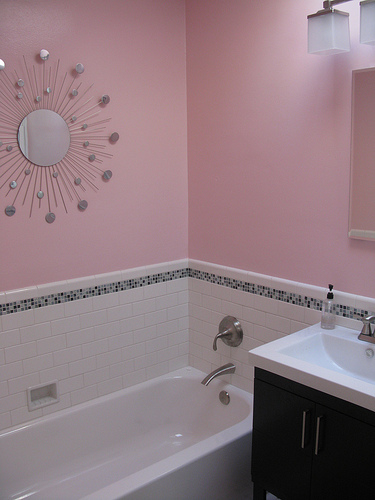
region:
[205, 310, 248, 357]
A bath tube water control lever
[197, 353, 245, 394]
A bathtub water faucet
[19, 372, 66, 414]
A bathtub soap dish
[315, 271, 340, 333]
A soap dispenser on a sink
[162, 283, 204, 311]
White tile on a bathtub wall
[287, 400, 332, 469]
Handles to a bathroom cabinet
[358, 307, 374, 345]
Part of a bathroom sink faucet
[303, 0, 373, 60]
Lights above a bathroom sink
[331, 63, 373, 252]
A bathroom mirror on a wall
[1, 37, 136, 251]
A silver and mirror design on a wall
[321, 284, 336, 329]
a soap dish bottle on top of the sink fixture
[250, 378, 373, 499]
black cabinet doors below the sink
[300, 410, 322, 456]
two metal handles on the cabinet doors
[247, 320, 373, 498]
a black and white sink fixture in the bathroom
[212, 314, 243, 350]
water faucet to the bathtub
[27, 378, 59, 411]
soap dish on the wall above the sink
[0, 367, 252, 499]
a white tub in the bathroom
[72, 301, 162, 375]
white ceramic tiles on the bathroom's walls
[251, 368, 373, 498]
a black cabinet below the sink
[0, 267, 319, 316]
black and white design to accent the wall tiles.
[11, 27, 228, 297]
a mirror on the wall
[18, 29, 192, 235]
a wall decoration on the wall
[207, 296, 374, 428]
a white bathroom sink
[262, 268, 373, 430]
a white sink with handsoap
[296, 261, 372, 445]
handsoap on a sink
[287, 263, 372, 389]
hand soap on a white sink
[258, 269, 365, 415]
handsoap on a bathroom wink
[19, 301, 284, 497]
a white bathroom tub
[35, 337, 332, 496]
a white bathroom bathtub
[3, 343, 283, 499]
a bathtub that is white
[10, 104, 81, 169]
mirror on the pink wall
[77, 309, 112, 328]
tile on the wall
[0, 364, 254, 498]
white bathtub by the tiles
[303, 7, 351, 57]
light in the bathroom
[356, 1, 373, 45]
light in the bathroom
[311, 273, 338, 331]
soap by the sink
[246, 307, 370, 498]
the sink is by the bathtub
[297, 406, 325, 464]
handles to the cabinet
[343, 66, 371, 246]
mirror above the sink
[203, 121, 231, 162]
the wall is pink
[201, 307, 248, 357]
a silver shower handle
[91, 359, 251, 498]
a white tub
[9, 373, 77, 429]
a space in the wall for soap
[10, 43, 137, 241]
a mirror hanging on the wall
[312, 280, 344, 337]
a clear plastic bottle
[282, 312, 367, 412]
a white bathroom sink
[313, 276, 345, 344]
a plastic bottle with a black lid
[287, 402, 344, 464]
silver handles on a cabinet doors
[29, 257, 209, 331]
black and grey tile on the wall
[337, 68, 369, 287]
a mirror hanging on the wall